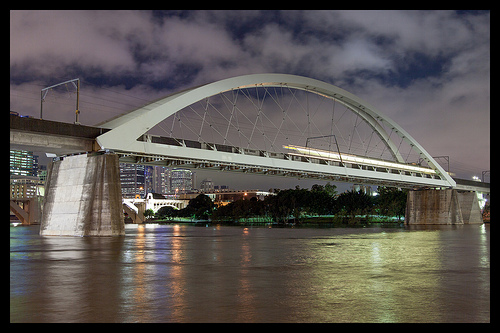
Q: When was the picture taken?
A: At night.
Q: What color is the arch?
A: White.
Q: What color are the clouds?
A: White.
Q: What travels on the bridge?
A: Motor vehicles.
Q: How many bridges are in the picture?
A: One.